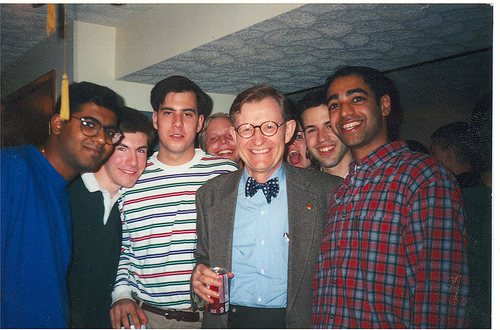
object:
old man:
[190, 84, 345, 327]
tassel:
[60, 72, 70, 119]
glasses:
[233, 120, 287, 138]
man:
[2, 81, 125, 328]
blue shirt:
[1, 144, 73, 329]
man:
[68, 105, 155, 327]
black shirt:
[67, 172, 123, 329]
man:
[111, 75, 240, 328]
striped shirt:
[111, 148, 240, 312]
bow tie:
[245, 176, 280, 204]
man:
[312, 65, 470, 329]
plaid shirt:
[311, 140, 471, 329]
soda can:
[206, 267, 231, 316]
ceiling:
[0, 2, 494, 95]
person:
[288, 120, 321, 169]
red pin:
[307, 204, 312, 207]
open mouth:
[289, 149, 303, 164]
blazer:
[190, 160, 345, 329]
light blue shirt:
[230, 164, 288, 308]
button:
[260, 270, 264, 274]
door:
[0, 69, 57, 148]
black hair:
[55, 81, 123, 115]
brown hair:
[120, 105, 158, 157]